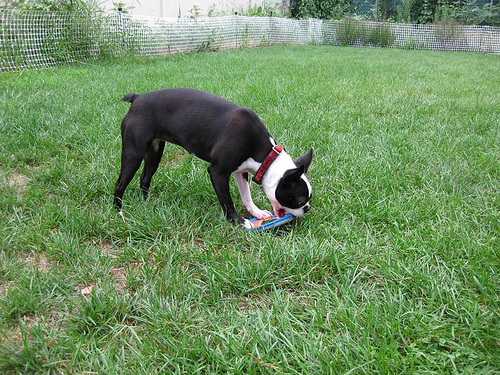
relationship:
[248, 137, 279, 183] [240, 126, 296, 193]
red collar around dog's neck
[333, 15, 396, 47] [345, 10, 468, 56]
weeds growing next to fence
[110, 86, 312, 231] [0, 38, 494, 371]
dog standing in grass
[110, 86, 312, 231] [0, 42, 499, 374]
dog in backyard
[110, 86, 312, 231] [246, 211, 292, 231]
dog with frisbee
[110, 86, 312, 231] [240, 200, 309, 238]
dog playing with frisbee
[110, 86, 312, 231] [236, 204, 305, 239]
dog chewing on frisbee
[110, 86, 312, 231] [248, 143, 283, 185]
dog wearing red collar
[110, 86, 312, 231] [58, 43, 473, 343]
dog playing in grass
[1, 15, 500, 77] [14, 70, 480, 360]
fence surrounds yard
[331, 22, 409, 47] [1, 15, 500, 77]
weeds growing around fence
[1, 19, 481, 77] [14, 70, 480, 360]
fence surrounds yard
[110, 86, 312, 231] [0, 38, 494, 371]
dog in grass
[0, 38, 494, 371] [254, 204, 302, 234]
grass playing with frisbee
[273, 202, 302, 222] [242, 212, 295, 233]
mouth holding frisbee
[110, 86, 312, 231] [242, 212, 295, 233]
dog holding frisbee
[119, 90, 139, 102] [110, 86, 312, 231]
bob tail belonging to dog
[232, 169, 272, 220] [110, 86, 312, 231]
front leg belonging to dog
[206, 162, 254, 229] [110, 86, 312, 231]
front leg belonging to dog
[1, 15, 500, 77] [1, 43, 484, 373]
fence surrounding yard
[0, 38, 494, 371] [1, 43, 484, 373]
grass growing in yard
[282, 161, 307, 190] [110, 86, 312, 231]
ear belonging to dog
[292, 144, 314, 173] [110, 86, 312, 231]
ear belonging to dog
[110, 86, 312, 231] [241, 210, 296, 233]
dog playing with frisbee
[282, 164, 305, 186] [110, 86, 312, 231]
ear belonging to dog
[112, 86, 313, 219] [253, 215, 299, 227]
dog biting frisbee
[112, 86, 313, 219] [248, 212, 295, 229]
dog playing with frisbee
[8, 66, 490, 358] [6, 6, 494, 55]
backyard has fence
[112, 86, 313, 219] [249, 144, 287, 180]
dog has collar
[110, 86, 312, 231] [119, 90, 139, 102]
dog with bob tail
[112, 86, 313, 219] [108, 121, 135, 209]
dog with leg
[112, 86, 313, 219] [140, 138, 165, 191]
dog with leg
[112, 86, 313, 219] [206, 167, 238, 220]
dog with front leg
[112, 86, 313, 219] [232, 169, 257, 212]
dog with front leg